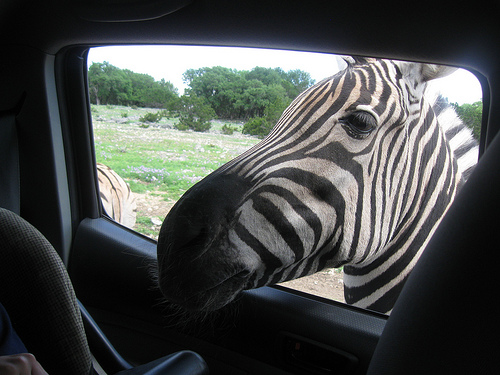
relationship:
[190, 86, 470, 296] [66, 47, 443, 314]
zebra in window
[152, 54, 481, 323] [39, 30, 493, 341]
zebra head in window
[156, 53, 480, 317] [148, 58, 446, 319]
zebra has head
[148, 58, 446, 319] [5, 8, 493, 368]
head in car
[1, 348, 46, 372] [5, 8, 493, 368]
person's hand in car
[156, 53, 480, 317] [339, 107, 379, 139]
zebra has eye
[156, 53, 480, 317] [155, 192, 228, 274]
zebra has nose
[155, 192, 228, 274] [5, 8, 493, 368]
nose in car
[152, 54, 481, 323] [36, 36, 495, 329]
zebra head in car window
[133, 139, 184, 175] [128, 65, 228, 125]
grass on savannah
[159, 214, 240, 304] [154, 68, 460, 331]
muzzle of zebra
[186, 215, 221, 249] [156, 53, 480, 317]
nostril of zebra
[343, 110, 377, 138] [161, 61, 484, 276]
eye of zebra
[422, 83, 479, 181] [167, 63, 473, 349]
mane of zebra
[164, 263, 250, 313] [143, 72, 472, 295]
mouth of zebra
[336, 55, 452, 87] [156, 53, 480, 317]
ears of zebra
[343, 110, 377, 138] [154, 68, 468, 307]
eye of zebra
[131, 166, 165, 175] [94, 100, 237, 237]
patch on ground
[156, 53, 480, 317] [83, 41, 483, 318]
zebra peeking through car window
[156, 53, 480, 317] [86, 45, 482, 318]
zebra peeking through car window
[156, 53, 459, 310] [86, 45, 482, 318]
head poking in car window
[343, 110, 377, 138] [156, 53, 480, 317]
eye belonging to zebra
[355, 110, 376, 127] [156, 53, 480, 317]
eyelash belonging to zebra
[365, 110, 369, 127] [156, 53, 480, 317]
eyelash belonging to zebra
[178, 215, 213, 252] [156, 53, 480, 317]
nostril belonging to zebra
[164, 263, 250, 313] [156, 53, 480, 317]
mouth belonging to zebra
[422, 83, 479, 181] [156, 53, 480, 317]
mane belonging to zebra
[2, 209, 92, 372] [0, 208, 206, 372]
side of car seat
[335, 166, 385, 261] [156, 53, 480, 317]
cheek of zebra